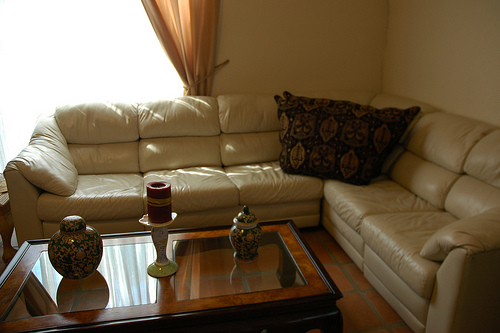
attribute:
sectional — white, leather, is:
[3, 75, 499, 327]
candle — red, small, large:
[140, 178, 182, 278]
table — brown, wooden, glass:
[2, 211, 345, 328]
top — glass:
[7, 226, 308, 322]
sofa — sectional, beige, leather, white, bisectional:
[7, 73, 499, 328]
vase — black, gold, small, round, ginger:
[47, 212, 105, 281]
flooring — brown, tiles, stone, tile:
[0, 217, 418, 330]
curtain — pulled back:
[140, 1, 229, 99]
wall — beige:
[218, 0, 499, 149]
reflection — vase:
[47, 270, 117, 325]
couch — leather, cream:
[7, 92, 492, 332]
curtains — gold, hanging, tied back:
[140, 2, 235, 106]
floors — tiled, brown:
[2, 210, 418, 330]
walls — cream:
[207, 1, 498, 125]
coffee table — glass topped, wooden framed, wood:
[1, 213, 345, 329]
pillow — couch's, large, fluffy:
[278, 89, 425, 185]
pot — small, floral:
[230, 202, 259, 261]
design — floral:
[230, 212, 260, 258]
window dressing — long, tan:
[137, 1, 230, 98]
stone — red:
[2, 205, 419, 331]